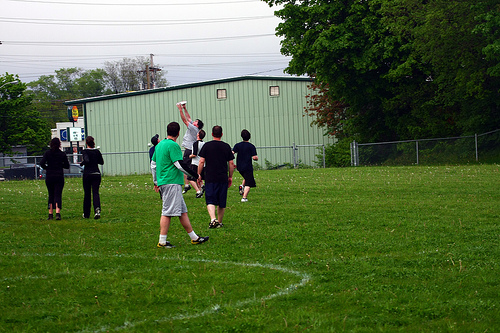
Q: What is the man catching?
A: Frisbee.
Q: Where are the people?
A: On a field.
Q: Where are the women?
A: To the left.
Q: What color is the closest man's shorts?
A: Grey.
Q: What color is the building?
A: Green.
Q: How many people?
A: Eight.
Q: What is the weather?
A: Clear.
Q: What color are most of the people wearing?
A: Black.